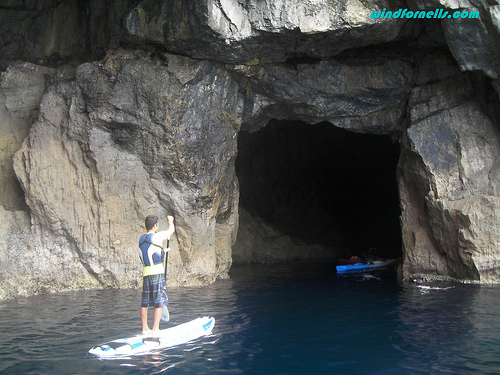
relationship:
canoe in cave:
[337, 256, 391, 282] [21, 8, 489, 298]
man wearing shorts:
[139, 215, 176, 339] [142, 277, 166, 307]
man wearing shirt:
[139, 215, 176, 339] [141, 235, 163, 273]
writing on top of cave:
[370, 5, 485, 24] [21, 8, 489, 298]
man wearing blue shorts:
[125, 215, 186, 312] [142, 277, 166, 307]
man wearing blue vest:
[125, 215, 186, 312] [135, 233, 167, 265]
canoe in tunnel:
[337, 256, 391, 282] [250, 126, 401, 277]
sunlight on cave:
[23, 146, 112, 252] [21, 8, 489, 298]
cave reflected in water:
[21, 8, 489, 298] [44, 265, 412, 368]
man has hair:
[125, 215, 186, 312] [143, 215, 155, 229]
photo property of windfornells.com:
[21, 8, 489, 298] [370, 5, 485, 24]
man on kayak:
[125, 215, 186, 312] [92, 319, 215, 364]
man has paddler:
[125, 215, 186, 312] [160, 219, 180, 323]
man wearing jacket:
[125, 215, 186, 312] [135, 233, 167, 265]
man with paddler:
[125, 215, 186, 312] [160, 219, 180, 323]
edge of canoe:
[193, 311, 217, 337] [337, 256, 391, 282]